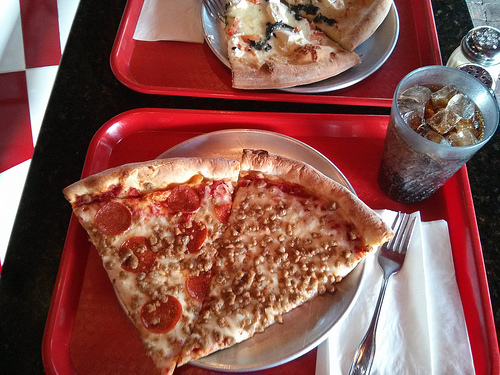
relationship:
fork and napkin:
[351, 211, 417, 374] [315, 207, 482, 373]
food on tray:
[208, 0, 397, 91] [110, 1, 446, 110]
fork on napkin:
[351, 211, 417, 374] [315, 207, 482, 373]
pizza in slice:
[62, 156, 242, 374] [174, 142, 395, 374]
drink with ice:
[376, 61, 500, 208] [399, 85, 480, 145]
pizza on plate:
[62, 156, 242, 374] [135, 125, 368, 373]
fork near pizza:
[351, 211, 417, 374] [62, 156, 242, 374]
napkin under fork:
[315, 207, 482, 373] [351, 211, 417, 374]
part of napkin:
[418, 217, 481, 371] [313, 207, 478, 375]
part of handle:
[343, 283, 385, 373] [348, 268, 400, 373]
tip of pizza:
[145, 332, 185, 369] [62, 156, 242, 374]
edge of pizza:
[113, 272, 149, 316] [62, 156, 242, 374]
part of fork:
[403, 222, 417, 232] [351, 211, 417, 374]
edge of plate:
[279, 328, 333, 355] [135, 125, 368, 373]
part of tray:
[418, 217, 481, 371] [48, 96, 499, 366]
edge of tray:
[112, 33, 163, 79] [110, 1, 446, 110]